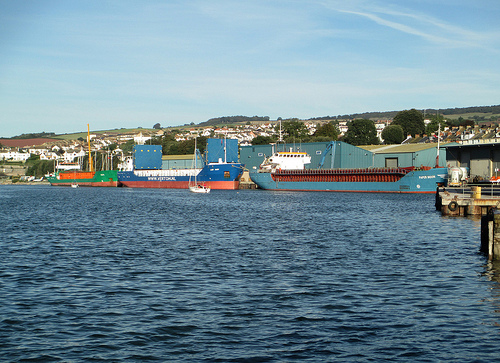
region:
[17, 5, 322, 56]
this is the sky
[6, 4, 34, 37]
the sky is blue in color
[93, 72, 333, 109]
the sky has some clouds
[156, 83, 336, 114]
the clouds are white in color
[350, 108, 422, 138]
these are the trees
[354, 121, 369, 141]
the leaves are green in color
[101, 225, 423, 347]
this is the water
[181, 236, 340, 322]
the water has ripples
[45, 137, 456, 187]
these are the boats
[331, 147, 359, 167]
the boats are blue in color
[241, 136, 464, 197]
light blue ship in port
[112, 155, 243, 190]
blue and red ship in port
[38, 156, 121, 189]
green and orange ship in port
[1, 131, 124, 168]
large group of white and red houses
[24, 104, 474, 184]
row of trees near harbor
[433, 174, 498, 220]
dock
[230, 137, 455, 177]
light blue buildings next to harbor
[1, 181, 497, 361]
dark blue body of water near shore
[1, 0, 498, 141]
light blue sky with a few wispy clouds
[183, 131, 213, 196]
small white boat near large ships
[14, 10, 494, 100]
overcast sky over the water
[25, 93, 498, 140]
hilly countryside with forest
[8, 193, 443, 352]
clear blue sea water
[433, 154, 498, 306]
part of a docking area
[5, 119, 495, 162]
housing community near seaside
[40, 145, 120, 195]
green transport ship for carrying goods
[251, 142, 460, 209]
a blue and white transport shipped docked at port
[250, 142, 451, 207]
another blue boat used for transporting materials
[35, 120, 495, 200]
three boats docked along the port area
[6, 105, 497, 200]
a scenic view of a coastal town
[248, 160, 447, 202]
short and long boat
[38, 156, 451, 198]
three boats that have been docked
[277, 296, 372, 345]
small ripples in the water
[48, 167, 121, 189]
green and orange boat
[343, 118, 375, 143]
dark green treetop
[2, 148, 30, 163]
white building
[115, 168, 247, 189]
blue and orange boat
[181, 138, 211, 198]
white sailboat in the water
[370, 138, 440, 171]
blue building with a green roof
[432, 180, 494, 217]
pier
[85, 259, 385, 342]
dark blue ocean waves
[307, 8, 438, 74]
blue sky with wispy clouds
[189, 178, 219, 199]
small white boat in water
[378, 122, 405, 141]
large round green tree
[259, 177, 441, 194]
blue base of boat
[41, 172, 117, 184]
green barge in water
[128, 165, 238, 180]
blue top of boat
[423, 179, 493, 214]
rusty dock in water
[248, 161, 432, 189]
blue and red barge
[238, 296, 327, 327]
choppy waves of blue water